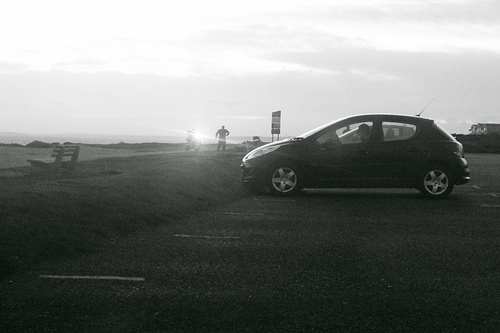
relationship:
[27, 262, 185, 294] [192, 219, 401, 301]
line on road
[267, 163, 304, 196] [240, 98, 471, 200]
tire on car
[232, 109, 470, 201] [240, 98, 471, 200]
fronttire on car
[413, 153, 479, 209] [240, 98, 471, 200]
back tire on car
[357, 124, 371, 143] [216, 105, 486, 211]
someone sitting on car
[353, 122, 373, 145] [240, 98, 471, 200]
someone sitting in their car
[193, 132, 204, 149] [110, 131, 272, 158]
sun shining near horizon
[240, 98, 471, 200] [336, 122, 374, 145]
car seen through window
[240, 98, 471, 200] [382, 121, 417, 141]
car seen through window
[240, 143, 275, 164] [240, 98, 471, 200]
headlight on car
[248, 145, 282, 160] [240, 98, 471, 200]
headlight on car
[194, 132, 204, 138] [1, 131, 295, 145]
sun setting above water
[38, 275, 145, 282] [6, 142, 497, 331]
line painted on ground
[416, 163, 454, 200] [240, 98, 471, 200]
back tire mounted on car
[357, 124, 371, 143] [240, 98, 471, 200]
someone sitting in car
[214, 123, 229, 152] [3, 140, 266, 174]
man standing on beach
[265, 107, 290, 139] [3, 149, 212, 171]
sign standing alongside beach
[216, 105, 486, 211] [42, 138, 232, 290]
car parked next to beach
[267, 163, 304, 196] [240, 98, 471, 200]
tire mounted on car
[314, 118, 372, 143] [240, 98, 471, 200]
window built into car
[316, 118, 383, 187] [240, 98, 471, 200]
side door of car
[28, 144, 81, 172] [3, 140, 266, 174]
bench at beach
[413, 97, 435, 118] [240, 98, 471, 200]
antennae on car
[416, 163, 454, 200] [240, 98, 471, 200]
back tire on car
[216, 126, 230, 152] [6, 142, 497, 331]
man on ground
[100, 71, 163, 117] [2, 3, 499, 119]
part of sky